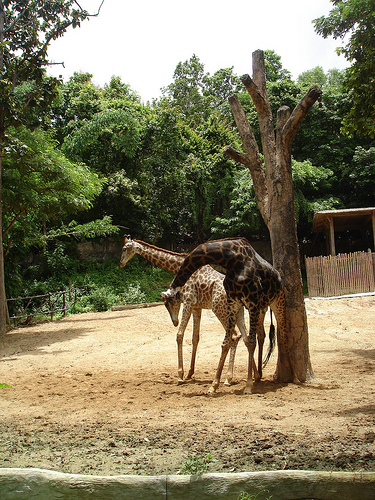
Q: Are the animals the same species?
A: Yes, all the animals are giraffes.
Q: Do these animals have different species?
A: No, all the animals are giraffes.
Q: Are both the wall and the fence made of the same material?
A: No, the wall is made of cement and the fence is made of wood.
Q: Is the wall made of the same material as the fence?
A: No, the wall is made of cement and the fence is made of wood.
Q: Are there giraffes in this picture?
A: Yes, there are giraffes.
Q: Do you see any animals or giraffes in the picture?
A: Yes, there are giraffes.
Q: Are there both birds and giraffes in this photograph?
A: No, there are giraffes but no birds.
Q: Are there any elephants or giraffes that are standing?
A: Yes, the giraffes are standing.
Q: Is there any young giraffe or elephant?
A: Yes, there are young giraffes.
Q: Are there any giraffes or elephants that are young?
A: Yes, the giraffes are young.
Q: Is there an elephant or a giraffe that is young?
A: Yes, the giraffes are young.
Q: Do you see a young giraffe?
A: Yes, there are young giraffes.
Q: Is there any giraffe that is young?
A: Yes, there are giraffes that are young.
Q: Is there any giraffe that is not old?
A: Yes, there are young giraffes.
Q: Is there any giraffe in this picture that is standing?
A: Yes, there are giraffes that are standing.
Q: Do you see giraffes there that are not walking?
A: Yes, there are giraffes that are standing .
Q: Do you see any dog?
A: No, there are no dogs.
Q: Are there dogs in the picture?
A: No, there are no dogs.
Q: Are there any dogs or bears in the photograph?
A: No, there are no dogs or bears.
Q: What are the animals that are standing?
A: The animals are giraffes.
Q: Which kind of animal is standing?
A: The animal is giraffes.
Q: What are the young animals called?
A: The animals are giraffes.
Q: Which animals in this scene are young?
A: The animals are giraffes.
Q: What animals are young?
A: The animals are giraffes.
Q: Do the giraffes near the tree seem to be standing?
A: Yes, the giraffes are standing.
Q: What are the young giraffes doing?
A: The giraffes are standing.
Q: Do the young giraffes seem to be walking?
A: No, the giraffes are standing.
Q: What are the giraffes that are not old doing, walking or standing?
A: The giraffes are standing.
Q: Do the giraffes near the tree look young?
A: Yes, the giraffes are young.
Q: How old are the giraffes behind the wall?
A: The giraffes are young.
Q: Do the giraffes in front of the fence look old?
A: No, the giraffes are young.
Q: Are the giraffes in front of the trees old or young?
A: The giraffes are young.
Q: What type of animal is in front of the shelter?
A: The animals are giraffes.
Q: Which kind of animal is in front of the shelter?
A: The animals are giraffes.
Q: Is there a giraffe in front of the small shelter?
A: Yes, there are giraffes in front of the shelter.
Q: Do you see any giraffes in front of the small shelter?
A: Yes, there are giraffes in front of the shelter.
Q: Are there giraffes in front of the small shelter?
A: Yes, there are giraffes in front of the shelter.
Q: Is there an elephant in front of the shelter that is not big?
A: No, there are giraffes in front of the shelter.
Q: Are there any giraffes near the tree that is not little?
A: Yes, there are giraffes near the tree.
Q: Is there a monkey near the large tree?
A: No, there are giraffes near the tree.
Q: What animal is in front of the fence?
A: The giraffes are in front of the fence.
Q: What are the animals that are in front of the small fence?
A: The animals are giraffes.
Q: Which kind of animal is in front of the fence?
A: The animals are giraffes.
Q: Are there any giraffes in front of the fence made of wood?
A: Yes, there are giraffes in front of the fence.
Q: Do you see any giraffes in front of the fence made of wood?
A: Yes, there are giraffes in front of the fence.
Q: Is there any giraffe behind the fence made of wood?
A: No, the giraffes are in front of the fence.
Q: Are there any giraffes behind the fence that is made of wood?
A: No, the giraffes are in front of the fence.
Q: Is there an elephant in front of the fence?
A: No, there are giraffes in front of the fence.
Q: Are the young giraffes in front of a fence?
A: Yes, the giraffes are in front of a fence.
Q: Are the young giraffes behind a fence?
A: No, the giraffes are in front of a fence.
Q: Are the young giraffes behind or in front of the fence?
A: The giraffes are in front of the fence.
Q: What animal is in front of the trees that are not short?
A: The giraffes are in front of the trees.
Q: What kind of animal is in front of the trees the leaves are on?
A: The animals are giraffes.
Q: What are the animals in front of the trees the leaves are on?
A: The animals are giraffes.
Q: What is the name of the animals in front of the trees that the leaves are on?
A: The animals are giraffes.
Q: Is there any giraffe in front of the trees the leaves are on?
A: Yes, there are giraffes in front of the trees.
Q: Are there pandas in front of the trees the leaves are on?
A: No, there are giraffes in front of the trees.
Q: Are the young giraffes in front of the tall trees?
A: Yes, the giraffes are in front of the trees.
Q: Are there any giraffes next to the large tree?
A: Yes, there are giraffes next to the tree.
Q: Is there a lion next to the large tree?
A: No, there are giraffes next to the tree.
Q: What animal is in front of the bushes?
A: The giraffes are in front of the bushes.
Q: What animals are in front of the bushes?
A: The animals are giraffes.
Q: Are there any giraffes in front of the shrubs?
A: Yes, there are giraffes in front of the shrubs.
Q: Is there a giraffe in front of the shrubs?
A: Yes, there are giraffes in front of the shrubs.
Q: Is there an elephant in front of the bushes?
A: No, there are giraffes in front of the bushes.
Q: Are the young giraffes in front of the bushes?
A: Yes, the giraffes are in front of the bushes.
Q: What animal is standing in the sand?
A: The giraffes are standing in the sand.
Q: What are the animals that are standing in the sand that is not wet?
A: The animals are giraffes.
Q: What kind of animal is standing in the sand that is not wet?
A: The animals are giraffes.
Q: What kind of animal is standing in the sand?
A: The animals are giraffes.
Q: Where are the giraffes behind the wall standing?
A: The giraffes are standing in the sand.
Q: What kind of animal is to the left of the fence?
A: The animals are giraffes.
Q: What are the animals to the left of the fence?
A: The animals are giraffes.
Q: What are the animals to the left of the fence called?
A: The animals are giraffes.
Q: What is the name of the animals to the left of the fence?
A: The animals are giraffes.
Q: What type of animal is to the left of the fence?
A: The animals are giraffes.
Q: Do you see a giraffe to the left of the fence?
A: Yes, there are giraffes to the left of the fence.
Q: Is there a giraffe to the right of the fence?
A: No, the giraffes are to the left of the fence.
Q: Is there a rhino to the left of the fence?
A: No, there are giraffes to the left of the fence.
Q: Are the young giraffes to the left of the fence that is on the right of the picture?
A: Yes, the giraffes are to the left of the fence.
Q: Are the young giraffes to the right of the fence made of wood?
A: No, the giraffes are to the left of the fence.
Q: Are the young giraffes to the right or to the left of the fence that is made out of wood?
A: The giraffes are to the left of the fence.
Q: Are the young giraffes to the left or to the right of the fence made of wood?
A: The giraffes are to the left of the fence.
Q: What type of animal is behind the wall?
A: The animals are giraffes.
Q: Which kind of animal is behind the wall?
A: The animals are giraffes.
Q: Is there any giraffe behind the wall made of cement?
A: Yes, there are giraffes behind the wall.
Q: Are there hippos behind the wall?
A: No, there are giraffes behind the wall.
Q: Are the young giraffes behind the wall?
A: Yes, the giraffes are behind the wall.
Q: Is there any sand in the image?
A: Yes, there is sand.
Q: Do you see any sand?
A: Yes, there is sand.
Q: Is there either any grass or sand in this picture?
A: Yes, there is sand.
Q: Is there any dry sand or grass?
A: Yes, there is dry sand.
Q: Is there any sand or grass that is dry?
A: Yes, the sand is dry.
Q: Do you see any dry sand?
A: Yes, there is dry sand.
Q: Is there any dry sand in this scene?
A: Yes, there is dry sand.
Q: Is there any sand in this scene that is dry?
A: Yes, there is sand that is dry.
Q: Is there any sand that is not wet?
A: Yes, there is dry sand.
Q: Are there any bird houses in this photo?
A: No, there are no bird houses.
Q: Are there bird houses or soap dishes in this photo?
A: No, there are no bird houses or soap dishes.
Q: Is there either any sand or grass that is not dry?
A: No, there is sand but it is dry.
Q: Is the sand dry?
A: Yes, the sand is dry.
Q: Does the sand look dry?
A: Yes, the sand is dry.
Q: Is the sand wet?
A: No, the sand is dry.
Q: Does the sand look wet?
A: No, the sand is dry.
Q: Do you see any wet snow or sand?
A: No, there is sand but it is dry.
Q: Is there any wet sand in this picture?
A: No, there is sand but it is dry.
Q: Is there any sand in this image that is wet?
A: No, there is sand but it is dry.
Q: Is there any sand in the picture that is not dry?
A: No, there is sand but it is dry.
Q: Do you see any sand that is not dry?
A: No, there is sand but it is dry.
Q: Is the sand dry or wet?
A: The sand is dry.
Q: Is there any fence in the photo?
A: Yes, there is a fence.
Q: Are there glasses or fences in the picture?
A: Yes, there is a fence.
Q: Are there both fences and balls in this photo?
A: No, there is a fence but no balls.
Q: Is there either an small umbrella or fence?
A: Yes, there is a small fence.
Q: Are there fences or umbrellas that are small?
A: Yes, the fence is small.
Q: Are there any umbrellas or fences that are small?
A: Yes, the fence is small.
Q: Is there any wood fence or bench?
A: Yes, there is a wood fence.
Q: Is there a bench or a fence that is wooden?
A: Yes, the fence is wooden.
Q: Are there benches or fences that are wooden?
A: Yes, the fence is wooden.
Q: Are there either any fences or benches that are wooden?
A: Yes, the fence is wooden.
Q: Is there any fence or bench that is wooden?
A: Yes, the fence is wooden.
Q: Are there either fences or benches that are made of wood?
A: Yes, the fence is made of wood.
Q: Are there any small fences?
A: Yes, there is a small fence.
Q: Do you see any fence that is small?
A: Yes, there is a fence that is small.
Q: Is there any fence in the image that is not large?
A: Yes, there is a small fence.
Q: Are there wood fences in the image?
A: Yes, there is a wood fence.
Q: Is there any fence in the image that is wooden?
A: Yes, there is a fence that is wooden.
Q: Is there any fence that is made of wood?
A: Yes, there is a fence that is made of wood.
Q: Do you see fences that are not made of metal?
A: Yes, there is a fence that is made of wood.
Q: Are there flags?
A: No, there are no flags.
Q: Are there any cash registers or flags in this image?
A: No, there are no flags or cash registers.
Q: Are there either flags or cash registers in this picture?
A: No, there are no flags or cash registers.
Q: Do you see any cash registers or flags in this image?
A: No, there are no flags or cash registers.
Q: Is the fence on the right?
A: Yes, the fence is on the right of the image.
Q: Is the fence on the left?
A: No, the fence is on the right of the image.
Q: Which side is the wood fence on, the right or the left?
A: The fence is on the right of the image.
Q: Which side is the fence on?
A: The fence is on the right of the image.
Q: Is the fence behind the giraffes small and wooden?
A: Yes, the fence is small and wooden.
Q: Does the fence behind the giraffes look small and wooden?
A: Yes, the fence is small and wooden.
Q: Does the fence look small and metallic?
A: No, the fence is small but wooden.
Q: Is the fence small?
A: Yes, the fence is small.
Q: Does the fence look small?
A: Yes, the fence is small.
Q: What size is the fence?
A: The fence is small.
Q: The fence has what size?
A: The fence is small.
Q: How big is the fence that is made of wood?
A: The fence is small.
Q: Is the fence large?
A: No, the fence is small.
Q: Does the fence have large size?
A: No, the fence is small.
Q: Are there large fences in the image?
A: No, there is a fence but it is small.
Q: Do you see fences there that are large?
A: No, there is a fence but it is small.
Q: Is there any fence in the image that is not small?
A: No, there is a fence but it is small.